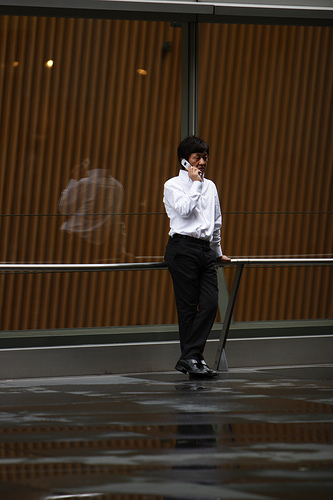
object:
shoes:
[175, 355, 210, 382]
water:
[2, 364, 331, 500]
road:
[0, 366, 331, 498]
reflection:
[175, 377, 219, 492]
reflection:
[59, 153, 139, 265]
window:
[0, 2, 332, 333]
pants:
[163, 234, 219, 357]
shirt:
[161, 169, 228, 257]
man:
[162, 135, 232, 379]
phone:
[181, 156, 197, 172]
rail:
[1, 256, 332, 273]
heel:
[176, 360, 186, 376]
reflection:
[11, 56, 153, 77]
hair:
[178, 135, 211, 160]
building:
[2, 1, 333, 381]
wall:
[0, 7, 332, 332]